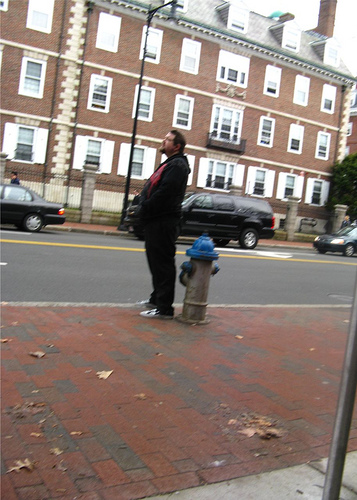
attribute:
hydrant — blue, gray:
[189, 231, 212, 324]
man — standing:
[152, 127, 178, 322]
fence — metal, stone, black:
[102, 176, 120, 218]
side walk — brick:
[143, 367, 198, 401]